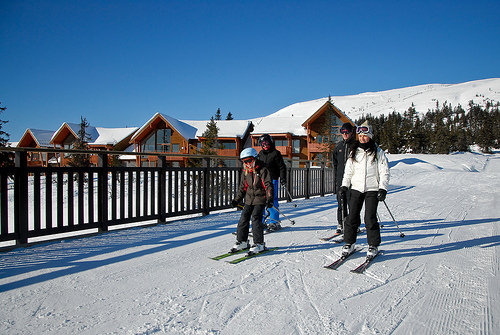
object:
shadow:
[343, 234, 499, 264]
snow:
[1, 75, 498, 331]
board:
[210, 243, 247, 261]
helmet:
[238, 147, 259, 160]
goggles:
[356, 126, 374, 136]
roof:
[256, 102, 328, 137]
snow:
[282, 118, 306, 130]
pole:
[378, 192, 407, 238]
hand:
[377, 187, 387, 202]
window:
[218, 139, 237, 150]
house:
[252, 99, 352, 166]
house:
[132, 109, 251, 170]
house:
[51, 120, 137, 173]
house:
[15, 122, 63, 175]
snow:
[1, 144, 500, 334]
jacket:
[340, 143, 392, 198]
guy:
[229, 145, 275, 255]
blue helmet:
[239, 147, 256, 160]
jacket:
[254, 148, 288, 180]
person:
[257, 133, 289, 232]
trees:
[351, 98, 500, 155]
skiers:
[340, 121, 395, 256]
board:
[350, 250, 383, 274]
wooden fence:
[0, 146, 335, 252]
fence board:
[77, 167, 85, 223]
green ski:
[211, 245, 249, 260]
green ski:
[226, 248, 272, 264]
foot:
[248, 242, 266, 254]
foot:
[229, 241, 251, 252]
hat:
[355, 118, 373, 140]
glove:
[376, 188, 386, 202]